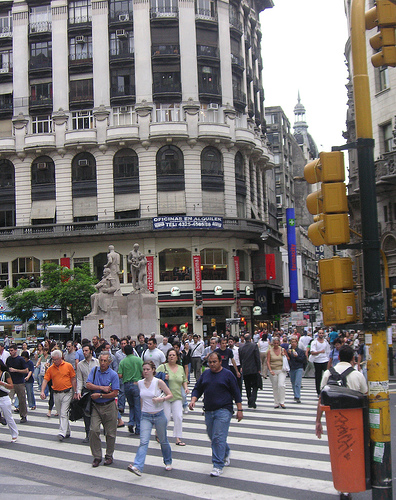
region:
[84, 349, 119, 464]
man wearing blue shirt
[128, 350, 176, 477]
woman wearing white tank top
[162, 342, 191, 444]
woman wearing green shirt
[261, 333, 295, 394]
woman wearing tan shirt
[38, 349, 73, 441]
man wearing orange shirt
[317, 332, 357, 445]
man wearing a black backpack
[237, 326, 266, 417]
man wearing a suit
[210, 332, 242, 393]
man wearing a black shirt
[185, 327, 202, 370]
man wearing a white shirt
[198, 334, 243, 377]
the head of a man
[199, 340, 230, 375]
the eye of a man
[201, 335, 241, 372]
the nose of a man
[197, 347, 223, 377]
the chin of a man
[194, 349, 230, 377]
the mouth of a man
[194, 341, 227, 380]
the neck of a man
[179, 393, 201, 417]
the hand of a man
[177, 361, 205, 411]
the arm of a man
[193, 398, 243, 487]
the leg of a man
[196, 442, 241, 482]
the feet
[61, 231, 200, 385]
statues outside a building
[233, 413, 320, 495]
white lines on a road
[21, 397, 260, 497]
white lines on a cross walk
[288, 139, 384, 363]
a yellow traffic light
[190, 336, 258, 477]
a man wearing blue jeans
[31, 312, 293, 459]
people walking outside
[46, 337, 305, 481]
people walking on a cross walk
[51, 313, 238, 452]
people standing outside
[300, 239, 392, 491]
a cross walk light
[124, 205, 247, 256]
a sign on a building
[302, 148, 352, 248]
Yellow traffic control light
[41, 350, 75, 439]
Man wearing orange shirt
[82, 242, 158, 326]
Statues made of concrete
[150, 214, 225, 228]
Blue sign with white letters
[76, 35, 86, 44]
Air conditioner in a window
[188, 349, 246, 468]
Man wearing long sleeved blue shirt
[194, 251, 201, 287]
Red banner with white leters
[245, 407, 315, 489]
Wide white strips painted on street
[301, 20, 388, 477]
Tall yellow post with traffic control light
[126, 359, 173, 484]
Woman wearing white sleeveless shirt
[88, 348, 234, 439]
the people are walking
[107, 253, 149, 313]
the statue is gray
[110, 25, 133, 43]
the ac is in the window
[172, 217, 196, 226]
the banner is blue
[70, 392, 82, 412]
he's carrying a briefcase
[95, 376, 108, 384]
the shirt is blue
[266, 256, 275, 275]
the banner is red